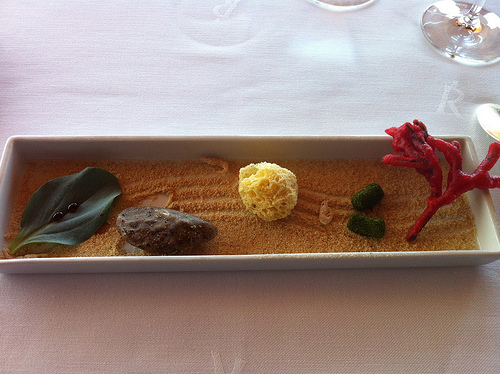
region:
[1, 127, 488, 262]
a tray with random silliness inside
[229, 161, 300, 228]
a piece of yellow sponge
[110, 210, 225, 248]
an oblong rock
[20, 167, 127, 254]
a black leaf with two black tones on it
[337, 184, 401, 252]
two piece of charcoal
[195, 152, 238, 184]
a curved orange rock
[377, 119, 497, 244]
a piece of red coral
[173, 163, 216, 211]
a patch of carefully tended too red sand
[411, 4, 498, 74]
the bottom of a glass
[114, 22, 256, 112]
a white table cloth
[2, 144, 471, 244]
food on the plate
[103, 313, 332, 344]
tablecloth on the table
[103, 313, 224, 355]
the tablecloth is white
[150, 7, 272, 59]
indentation on the tablecloth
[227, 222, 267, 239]
sugar on the plate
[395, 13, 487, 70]
bottom of the glass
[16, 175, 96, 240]
leaf on the plate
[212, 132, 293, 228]
yellow food on plate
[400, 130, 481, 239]
red stem on plate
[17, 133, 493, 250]
the plate is rectangular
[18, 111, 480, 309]
a small zen rock garden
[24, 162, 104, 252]
a small green leaf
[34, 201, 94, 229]
a few small black beans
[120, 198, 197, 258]
a small brown stone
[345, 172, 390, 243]
two small green stones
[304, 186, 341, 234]
some small sea shell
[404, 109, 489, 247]
a red colored sea creature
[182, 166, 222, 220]
lines drawn in the sand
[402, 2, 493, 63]
the bottom of a wine glass